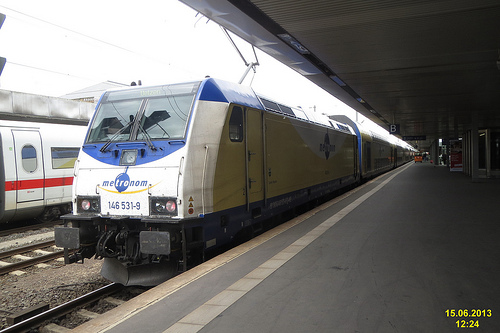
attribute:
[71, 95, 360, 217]
train — passenger, late, transporting, stopped, here, white, blue, yellow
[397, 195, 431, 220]
station — loading, grey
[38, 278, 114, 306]
tracks — dark, grey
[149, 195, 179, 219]
headlights — white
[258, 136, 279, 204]
door — here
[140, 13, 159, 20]
sky — here, bright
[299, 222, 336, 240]
line — here, yellow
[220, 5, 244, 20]
metal — here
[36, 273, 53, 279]
rock — small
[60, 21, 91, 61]
wire — her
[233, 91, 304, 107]
roof — here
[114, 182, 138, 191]
writing — here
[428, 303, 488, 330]
stamp — here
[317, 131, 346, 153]
window — large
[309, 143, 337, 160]
name — blue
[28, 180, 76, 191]
stripe — red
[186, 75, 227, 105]
paint — blue